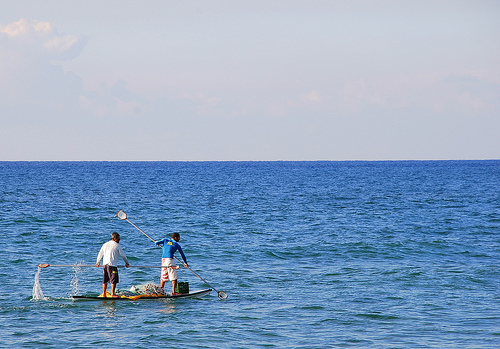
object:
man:
[155, 232, 190, 299]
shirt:
[153, 238, 189, 261]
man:
[95, 231, 130, 299]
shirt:
[96, 241, 129, 266]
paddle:
[116, 206, 230, 302]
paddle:
[38, 263, 182, 271]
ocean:
[0, 160, 497, 349]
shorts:
[99, 267, 119, 284]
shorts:
[159, 257, 178, 283]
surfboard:
[71, 287, 213, 301]